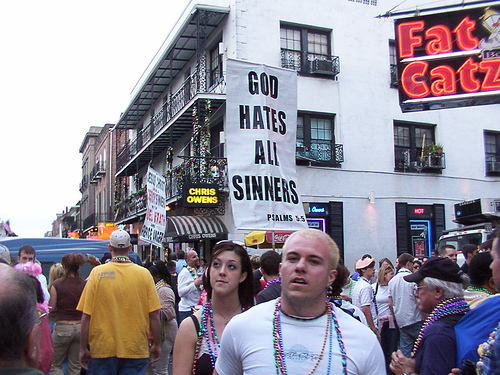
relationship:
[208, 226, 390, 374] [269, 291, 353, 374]
man wears beads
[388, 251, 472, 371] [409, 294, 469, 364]
man wears beads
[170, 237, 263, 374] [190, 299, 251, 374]
woman wears beads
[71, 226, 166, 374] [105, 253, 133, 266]
man wears beads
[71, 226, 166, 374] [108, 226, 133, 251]
man wears cap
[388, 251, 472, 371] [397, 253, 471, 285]
man wears cap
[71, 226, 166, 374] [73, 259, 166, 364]
man wears shirt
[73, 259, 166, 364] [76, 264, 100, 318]
shirt has sleeve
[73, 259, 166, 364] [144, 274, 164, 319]
shirt has sleeve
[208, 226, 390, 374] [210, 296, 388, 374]
man wears shirt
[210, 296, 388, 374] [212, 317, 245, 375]
shirt has sleeve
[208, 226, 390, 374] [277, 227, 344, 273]
man has hair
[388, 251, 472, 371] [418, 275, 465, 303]
man has hair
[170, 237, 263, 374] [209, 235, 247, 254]
woman has glasses